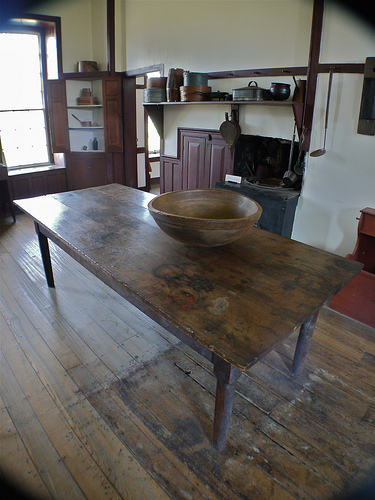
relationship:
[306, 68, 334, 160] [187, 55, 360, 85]
ladle on a rack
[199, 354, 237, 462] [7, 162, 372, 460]
leg on table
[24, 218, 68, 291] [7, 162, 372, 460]
wooden leg on a table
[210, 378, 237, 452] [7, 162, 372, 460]
leg on a table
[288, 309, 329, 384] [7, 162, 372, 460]
wooden leg on a table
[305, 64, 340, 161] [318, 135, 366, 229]
untensil on wall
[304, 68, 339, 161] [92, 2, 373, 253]
ladle hanging from wall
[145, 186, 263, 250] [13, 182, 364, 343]
bowl on table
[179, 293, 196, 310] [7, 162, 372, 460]
paint on table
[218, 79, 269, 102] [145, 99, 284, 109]
container on a shelf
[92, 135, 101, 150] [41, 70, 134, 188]
bottle in a cabinet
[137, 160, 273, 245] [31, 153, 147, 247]
bowl on table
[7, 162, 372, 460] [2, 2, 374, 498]
table is sitting in a kitchen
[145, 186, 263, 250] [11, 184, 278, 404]
bowl on the table